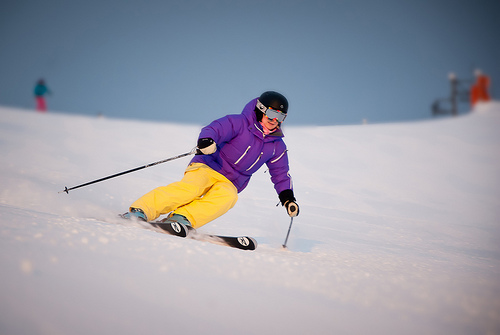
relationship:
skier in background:
[29, 74, 57, 113] [1, 1, 500, 122]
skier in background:
[469, 72, 493, 106] [1, 1, 500, 122]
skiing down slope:
[51, 139, 327, 248] [298, 102, 441, 319]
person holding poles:
[148, 81, 305, 242] [51, 139, 327, 248]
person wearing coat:
[148, 81, 305, 242] [199, 114, 299, 189]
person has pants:
[148, 81, 305, 242] [134, 153, 238, 237]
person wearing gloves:
[148, 81, 305, 242] [194, 121, 308, 245]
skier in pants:
[148, 81, 305, 242] [134, 153, 238, 237]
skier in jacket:
[70, 104, 312, 231] [199, 114, 299, 189]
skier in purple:
[70, 104, 312, 231] [213, 124, 271, 170]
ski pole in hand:
[282, 216, 296, 247] [285, 192, 305, 215]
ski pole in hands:
[62, 145, 200, 193] [197, 139, 217, 154]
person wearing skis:
[148, 81, 305, 242] [51, 139, 327, 248]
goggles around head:
[252, 104, 287, 125] [246, 79, 298, 135]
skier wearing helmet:
[70, 104, 312, 231] [250, 90, 292, 116]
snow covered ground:
[318, 152, 483, 311] [3, 235, 494, 329]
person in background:
[469, 72, 493, 106] [1, 1, 500, 122]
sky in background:
[7, 2, 476, 73] [1, 1, 500, 122]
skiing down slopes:
[51, 139, 327, 248] [298, 102, 441, 319]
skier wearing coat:
[70, 104, 312, 231] [199, 114, 299, 189]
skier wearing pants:
[70, 104, 312, 231] [134, 153, 238, 237]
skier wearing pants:
[29, 74, 57, 113] [33, 93, 48, 110]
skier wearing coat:
[29, 74, 57, 113] [33, 84, 53, 95]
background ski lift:
[1, 1, 500, 122] [430, 62, 476, 122]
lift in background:
[430, 62, 476, 122] [1, 1, 500, 122]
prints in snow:
[38, 189, 122, 251] [6, 131, 60, 324]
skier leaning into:
[70, 104, 312, 231] [272, 119, 382, 255]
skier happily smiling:
[70, 104, 312, 231] [258, 117, 283, 134]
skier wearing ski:
[70, 104, 312, 231] [127, 222, 188, 237]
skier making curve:
[70, 104, 312, 231] [95, 121, 351, 289]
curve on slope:
[95, 121, 351, 289] [298, 102, 441, 319]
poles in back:
[51, 139, 327, 248] [181, 100, 220, 198]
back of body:
[181, 100, 220, 198] [148, 81, 305, 242]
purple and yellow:
[213, 124, 271, 170] [189, 177, 227, 213]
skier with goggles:
[70, 104, 312, 231] [258, 107, 292, 124]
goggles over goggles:
[252, 104, 287, 125] [258, 107, 292, 124]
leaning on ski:
[194, 121, 308, 245] [127, 222, 188, 237]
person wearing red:
[469, 72, 493, 106] [469, 82, 489, 105]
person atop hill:
[469, 72, 493, 106] [378, 98, 500, 204]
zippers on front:
[233, 141, 264, 174] [223, 121, 271, 193]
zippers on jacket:
[233, 141, 264, 174] [199, 114, 299, 189]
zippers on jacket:
[235, 140, 291, 177] [199, 114, 299, 189]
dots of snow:
[29, 206, 143, 288] [6, 131, 60, 324]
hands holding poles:
[193, 141, 299, 217] [51, 139, 327, 248]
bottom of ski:
[124, 215, 258, 254] [127, 222, 188, 237]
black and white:
[159, 217, 173, 235] [169, 221, 183, 234]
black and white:
[225, 236, 240, 245] [232, 234, 249, 247]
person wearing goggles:
[130, 90, 299, 226] [258, 107, 292, 124]